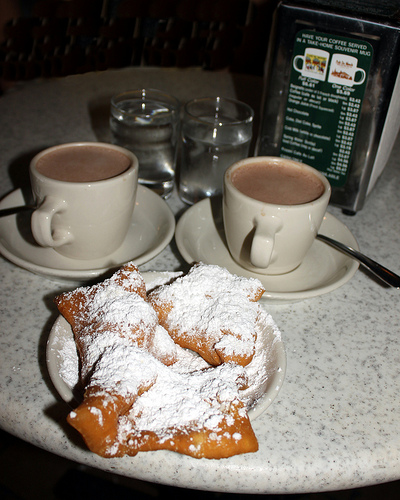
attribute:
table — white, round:
[3, 65, 398, 494]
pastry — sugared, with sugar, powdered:
[51, 261, 179, 385]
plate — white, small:
[41, 268, 290, 426]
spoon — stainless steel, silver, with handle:
[318, 230, 399, 294]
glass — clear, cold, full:
[172, 94, 256, 208]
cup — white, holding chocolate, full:
[24, 143, 141, 261]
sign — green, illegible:
[270, 30, 376, 190]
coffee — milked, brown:
[230, 160, 325, 208]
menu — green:
[275, 26, 373, 189]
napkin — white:
[366, 66, 399, 200]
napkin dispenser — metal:
[252, 0, 398, 219]